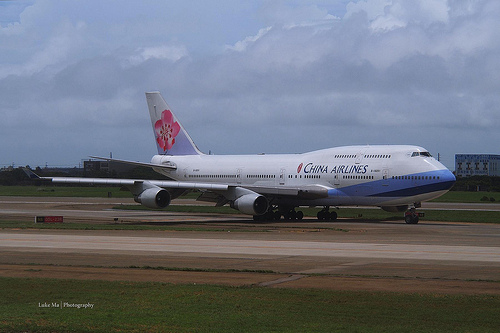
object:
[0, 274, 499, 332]
grass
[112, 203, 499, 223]
grass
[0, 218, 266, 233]
grass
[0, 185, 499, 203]
grass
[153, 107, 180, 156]
flower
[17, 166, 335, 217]
wing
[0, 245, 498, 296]
dirt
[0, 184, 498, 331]
ground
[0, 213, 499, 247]
dirt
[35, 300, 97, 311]
watermark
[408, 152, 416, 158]
windows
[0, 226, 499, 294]
runway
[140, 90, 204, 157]
tail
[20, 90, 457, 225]
airplane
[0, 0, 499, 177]
sky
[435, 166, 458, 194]
nose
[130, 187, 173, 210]
engines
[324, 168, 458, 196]
stripe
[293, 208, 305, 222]
wheels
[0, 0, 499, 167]
cloud